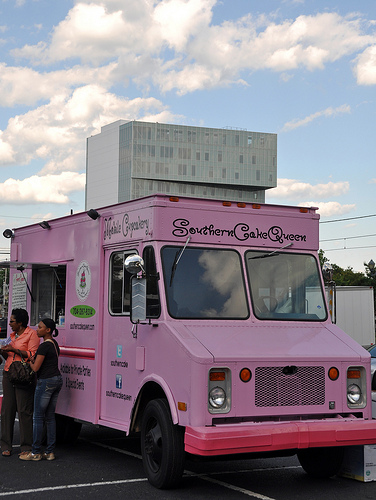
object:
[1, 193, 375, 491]
truck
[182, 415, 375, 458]
bumper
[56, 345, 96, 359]
stripe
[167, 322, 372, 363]
hood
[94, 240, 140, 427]
door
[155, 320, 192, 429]
fender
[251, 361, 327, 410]
grille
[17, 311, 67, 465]
people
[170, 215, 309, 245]
writing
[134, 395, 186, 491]
tire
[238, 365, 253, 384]
turn signal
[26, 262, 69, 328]
window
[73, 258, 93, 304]
logo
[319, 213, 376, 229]
electrical lines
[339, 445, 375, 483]
box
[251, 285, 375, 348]
building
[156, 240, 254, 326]
windshield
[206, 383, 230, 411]
headlight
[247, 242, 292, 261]
windshield wiper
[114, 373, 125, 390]
facebook logo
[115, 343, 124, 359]
twitter logo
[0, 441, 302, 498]
lines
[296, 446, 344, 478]
tire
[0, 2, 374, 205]
clouds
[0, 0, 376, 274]
sky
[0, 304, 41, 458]
woman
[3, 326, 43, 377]
shirt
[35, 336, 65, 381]
shirt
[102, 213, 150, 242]
writing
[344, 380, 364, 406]
headlight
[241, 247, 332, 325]
windshield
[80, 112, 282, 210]
building